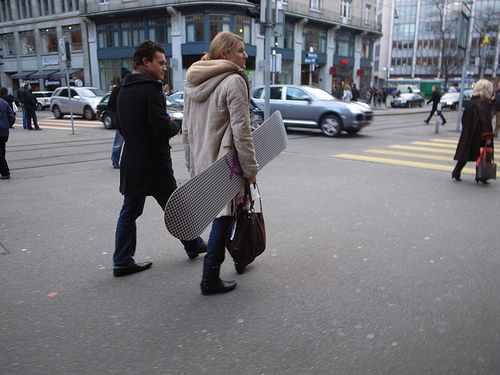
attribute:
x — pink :
[222, 149, 242, 182]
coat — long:
[453, 96, 492, 160]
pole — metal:
[59, 37, 74, 64]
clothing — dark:
[112, 71, 199, 260]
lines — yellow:
[348, 113, 478, 195]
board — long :
[162, 104, 291, 241]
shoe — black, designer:
[113, 258, 152, 276]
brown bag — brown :
[477, 145, 499, 182]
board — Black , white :
[158, 111, 292, 247]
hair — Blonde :
[204, 27, 248, 77]